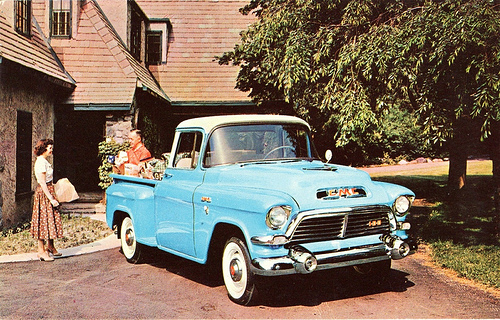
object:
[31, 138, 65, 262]
woman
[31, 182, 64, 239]
skirt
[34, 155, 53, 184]
blouse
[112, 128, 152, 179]
man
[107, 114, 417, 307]
truck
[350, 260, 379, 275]
wheel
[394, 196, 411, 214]
headlight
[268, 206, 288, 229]
headlight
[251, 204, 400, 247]
grill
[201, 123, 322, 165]
windshield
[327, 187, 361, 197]
logo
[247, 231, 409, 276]
bumper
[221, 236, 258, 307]
wheel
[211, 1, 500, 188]
tree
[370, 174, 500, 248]
shadow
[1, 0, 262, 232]
house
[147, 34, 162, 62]
window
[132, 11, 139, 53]
window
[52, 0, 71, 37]
window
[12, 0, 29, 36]
window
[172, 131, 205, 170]
window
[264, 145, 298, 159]
steering wheel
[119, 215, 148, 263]
white wall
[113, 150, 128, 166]
groceries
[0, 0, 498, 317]
yard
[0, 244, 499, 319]
driveway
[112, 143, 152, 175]
shirt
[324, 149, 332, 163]
rear view mirror